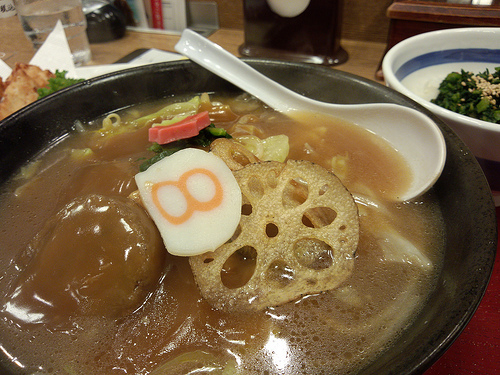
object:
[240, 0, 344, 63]
holder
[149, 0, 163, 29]
mail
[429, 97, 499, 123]
vegetable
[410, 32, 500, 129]
salad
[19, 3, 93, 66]
water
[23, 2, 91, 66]
glass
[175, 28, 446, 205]
spoon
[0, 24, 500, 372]
food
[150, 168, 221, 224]
eight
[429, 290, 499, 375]
place mat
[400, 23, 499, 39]
ring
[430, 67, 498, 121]
green vegetables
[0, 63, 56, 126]
bread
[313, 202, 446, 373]
soup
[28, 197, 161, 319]
meat piece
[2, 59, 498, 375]
bowl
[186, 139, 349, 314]
vegetable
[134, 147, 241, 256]
cooked egg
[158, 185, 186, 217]
yolk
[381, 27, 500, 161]
bowl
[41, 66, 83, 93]
leaves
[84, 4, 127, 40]
glass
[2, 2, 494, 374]
table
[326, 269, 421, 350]
noodles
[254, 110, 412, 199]
broth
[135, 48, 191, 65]
napkin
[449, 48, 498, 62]
blue trim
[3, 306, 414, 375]
stew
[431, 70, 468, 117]
vegetable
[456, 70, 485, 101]
sauce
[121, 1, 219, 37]
holder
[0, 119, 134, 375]
soup